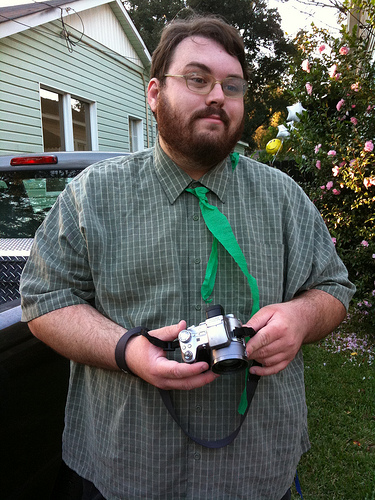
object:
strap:
[115, 326, 263, 449]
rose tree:
[251, 24, 374, 313]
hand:
[241, 301, 305, 375]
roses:
[304, 76, 345, 141]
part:
[0, 0, 72, 19]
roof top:
[0, 0, 152, 73]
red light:
[10, 155, 59, 166]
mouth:
[196, 114, 223, 123]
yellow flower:
[266, 138, 284, 156]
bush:
[119, 0, 375, 331]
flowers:
[348, 130, 374, 205]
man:
[19, 8, 357, 500]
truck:
[0, 151, 133, 421]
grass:
[292, 303, 375, 497]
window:
[34, 81, 98, 152]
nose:
[205, 82, 226, 107]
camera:
[114, 304, 262, 449]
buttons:
[194, 257, 200, 263]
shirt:
[19, 135, 357, 500]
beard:
[155, 85, 246, 168]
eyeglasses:
[158, 72, 248, 99]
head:
[145, 6, 251, 180]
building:
[0, 0, 250, 156]